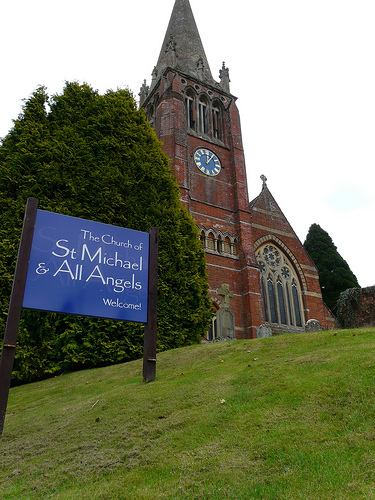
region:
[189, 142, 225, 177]
the blue clock on the building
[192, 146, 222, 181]
the gold hands of the clock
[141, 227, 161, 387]
a wooden post for the sign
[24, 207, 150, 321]
the blue sign for the church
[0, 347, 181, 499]
The sign base in the hillside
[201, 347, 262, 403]
leaves on the grass hill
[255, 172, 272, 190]
a cross on the church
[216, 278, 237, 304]
A cross on the tombstone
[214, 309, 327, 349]
tombstones in front of the church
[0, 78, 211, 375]
The tree behind the blue sign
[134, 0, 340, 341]
a church with a clock tower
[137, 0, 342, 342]
a brick church and tower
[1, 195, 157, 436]
The Church of St Michael & All Angels blue sign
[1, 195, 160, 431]
a Welcome sign to the Church of St Michael & Angels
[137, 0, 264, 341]
The Church of St Michael & All Angels clock tower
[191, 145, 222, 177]
a blue face clock on the tower of the church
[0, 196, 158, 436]
a blue church sign on two black poles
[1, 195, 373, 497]
the church's sign on poles standing on a hill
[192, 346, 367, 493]
green grass on the ground of the church property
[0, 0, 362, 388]
two green trees on the sides of the church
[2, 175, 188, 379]
a sign on the grass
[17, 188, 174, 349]
the sign is blue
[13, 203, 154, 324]
the letters are white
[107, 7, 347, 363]
the building is a church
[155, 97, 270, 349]
the building is reddish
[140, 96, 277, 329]
the building is made of bricks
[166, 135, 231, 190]
a clock on the front of the building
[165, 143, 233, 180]
the clock is black and gold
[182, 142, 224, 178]
the numbers are roman numerals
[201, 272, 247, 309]
statue of a cross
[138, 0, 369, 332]
Church of St. Michael's and All Angels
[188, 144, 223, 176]
clock in church tower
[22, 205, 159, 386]
sign for Church of St. Michael and All Angels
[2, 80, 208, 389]
large green trees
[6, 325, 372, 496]
small grassy hill in front of a church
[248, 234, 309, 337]
stained glass windows in a church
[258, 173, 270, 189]
cross on top of a church building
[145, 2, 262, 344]
church bell tower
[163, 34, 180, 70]
statue at corner of church roof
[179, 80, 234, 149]
arches in the church bell tower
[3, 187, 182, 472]
This is a church poster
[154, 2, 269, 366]
This is a church building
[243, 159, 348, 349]
This is a church building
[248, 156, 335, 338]
This is a brick building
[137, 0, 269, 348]
This is a brick building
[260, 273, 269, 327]
Window of a building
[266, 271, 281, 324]
Window of a building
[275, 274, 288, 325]
Window of a building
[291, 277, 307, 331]
Window of a building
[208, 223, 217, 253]
Window of a building